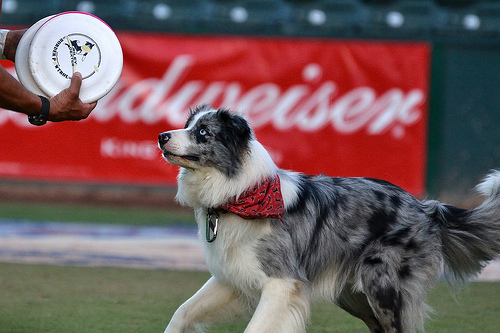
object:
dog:
[157, 102, 500, 333]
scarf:
[211, 172, 285, 224]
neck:
[193, 162, 294, 219]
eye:
[198, 128, 211, 136]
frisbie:
[14, 10, 123, 103]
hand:
[47, 71, 98, 122]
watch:
[27, 95, 51, 127]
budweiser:
[0, 53, 428, 139]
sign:
[97, 136, 283, 165]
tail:
[436, 167, 499, 287]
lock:
[206, 206, 221, 243]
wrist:
[25, 90, 59, 123]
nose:
[157, 131, 174, 144]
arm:
[0, 64, 49, 122]